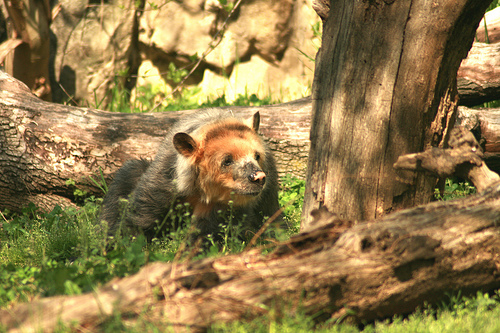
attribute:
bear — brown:
[103, 112, 280, 244]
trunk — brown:
[1, 39, 498, 219]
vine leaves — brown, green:
[160, 62, 202, 98]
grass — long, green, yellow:
[0, 183, 500, 331]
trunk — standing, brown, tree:
[304, 2, 491, 237]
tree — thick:
[324, 2, 466, 207]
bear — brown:
[95, 103, 292, 259]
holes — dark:
[357, 227, 437, 281]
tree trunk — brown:
[1, 145, 496, 330]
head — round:
[185, 130, 271, 213]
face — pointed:
[213, 145, 264, 189]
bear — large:
[85, 104, 318, 251]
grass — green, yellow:
[371, 292, 496, 331]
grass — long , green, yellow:
[23, 199, 121, 290]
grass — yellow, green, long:
[1, 72, 498, 331]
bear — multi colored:
[136, 116, 295, 222]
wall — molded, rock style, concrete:
[3, 8, 324, 112]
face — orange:
[190, 129, 272, 202]